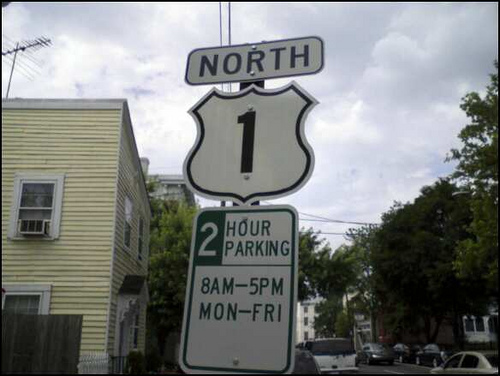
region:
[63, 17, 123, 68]
white clouds in blue sky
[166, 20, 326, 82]
black and white street sign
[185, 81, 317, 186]
black and white street sign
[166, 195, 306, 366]
green and white street sign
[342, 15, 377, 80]
white clouds in blue sky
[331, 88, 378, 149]
white clouds in blue sky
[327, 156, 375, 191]
white clouds in blue sky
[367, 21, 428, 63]
white clouds in blue sky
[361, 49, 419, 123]
white clouds in blue sky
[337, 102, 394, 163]
white clouds in blue sky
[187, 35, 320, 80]
North signage on pole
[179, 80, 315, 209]
Route one indicator sign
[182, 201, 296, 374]
Two hour parking sign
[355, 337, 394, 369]
A amsall grey car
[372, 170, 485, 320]
A small green tree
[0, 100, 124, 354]
The side of a white house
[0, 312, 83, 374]
A small brown fence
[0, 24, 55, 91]
An antenna on a roof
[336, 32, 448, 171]
Clouds flying in sky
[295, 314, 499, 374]
A busy road way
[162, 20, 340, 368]
signs on a sign post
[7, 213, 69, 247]
air conditioner in a window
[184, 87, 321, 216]
marker dictating road route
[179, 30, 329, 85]
directional marker on a street sign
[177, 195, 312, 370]
parking limit sign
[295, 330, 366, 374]
SUV parked on the side of the street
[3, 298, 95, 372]
a tall wooden fence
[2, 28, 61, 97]
television antenna on top of a building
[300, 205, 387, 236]
overhead powerlines in a city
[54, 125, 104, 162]
yellow siding on a building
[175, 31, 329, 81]
white street sign on pole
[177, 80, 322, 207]
white highway sign on pole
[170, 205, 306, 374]
white parking sign on pole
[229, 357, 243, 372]
silver screw on bottom of sign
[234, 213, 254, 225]
silver screw on top of sign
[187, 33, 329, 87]
black lettering on sign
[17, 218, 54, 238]
a.c. unit in the window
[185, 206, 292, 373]
green writing on the sign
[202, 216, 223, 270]
white number on sign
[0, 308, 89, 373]
brown wooden fence by house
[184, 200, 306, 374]
green and white sign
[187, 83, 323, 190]
black and white sign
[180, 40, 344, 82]
white and black sign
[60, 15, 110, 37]
white clouds in blue sky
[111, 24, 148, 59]
white clouds in blue sky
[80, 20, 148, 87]
white clouds in blue sky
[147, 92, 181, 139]
white clouds in blue sky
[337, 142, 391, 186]
white clouds in blue sky